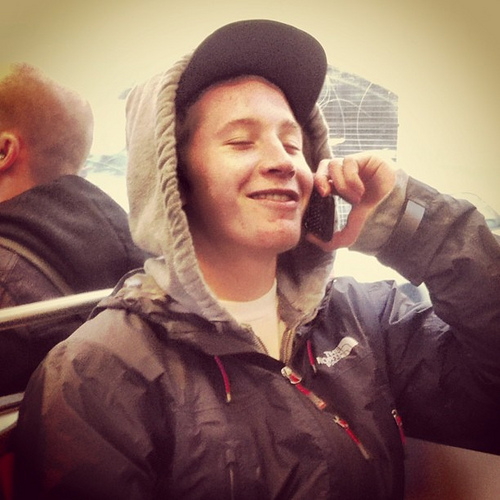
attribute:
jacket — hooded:
[56, 275, 456, 473]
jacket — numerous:
[64, 287, 453, 492]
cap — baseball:
[184, 14, 325, 105]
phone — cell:
[295, 180, 344, 253]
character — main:
[149, 60, 396, 443]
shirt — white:
[230, 291, 313, 349]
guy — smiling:
[194, 133, 314, 258]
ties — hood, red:
[208, 338, 330, 395]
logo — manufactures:
[317, 330, 358, 365]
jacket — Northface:
[81, 270, 377, 460]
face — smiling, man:
[203, 99, 311, 262]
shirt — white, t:
[208, 275, 314, 387]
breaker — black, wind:
[64, 259, 424, 463]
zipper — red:
[274, 360, 387, 472]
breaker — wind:
[26, 273, 396, 495]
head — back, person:
[7, 62, 97, 180]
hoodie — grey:
[116, 44, 350, 305]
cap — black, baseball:
[178, 19, 341, 103]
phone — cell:
[295, 171, 341, 245]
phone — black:
[306, 183, 341, 244]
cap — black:
[179, 10, 332, 94]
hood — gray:
[113, 52, 353, 308]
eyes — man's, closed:
[225, 120, 305, 155]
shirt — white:
[200, 287, 294, 366]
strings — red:
[208, 339, 322, 397]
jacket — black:
[56, 279, 409, 457]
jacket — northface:
[67, 280, 412, 445]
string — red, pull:
[203, 351, 240, 408]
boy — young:
[125, 54, 347, 368]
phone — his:
[296, 193, 338, 245]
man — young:
[130, 25, 390, 445]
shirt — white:
[217, 278, 306, 368]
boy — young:
[178, 81, 335, 353]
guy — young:
[171, 68, 336, 283]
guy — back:
[12, 60, 130, 296]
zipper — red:
[273, 358, 370, 452]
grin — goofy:
[234, 184, 319, 217]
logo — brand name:
[309, 328, 363, 376]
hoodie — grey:
[110, 69, 237, 354]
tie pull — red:
[199, 360, 240, 410]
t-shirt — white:
[235, 290, 300, 362]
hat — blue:
[182, 49, 322, 99]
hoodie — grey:
[103, 48, 263, 287]